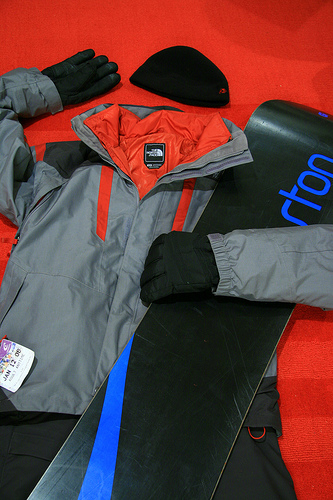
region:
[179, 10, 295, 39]
bright orange surface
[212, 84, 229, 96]
orange logo on black cap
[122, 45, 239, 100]
black cap on surface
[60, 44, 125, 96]
fingers on black gloves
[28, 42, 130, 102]
pair of black gloves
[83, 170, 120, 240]
orange lining on jacket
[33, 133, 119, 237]
black and gray jacket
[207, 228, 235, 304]
edge of gray jacket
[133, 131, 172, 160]
silver and black logo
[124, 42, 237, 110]
Black knitted ski hat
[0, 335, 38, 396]
Ski lift access tag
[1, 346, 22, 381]
Printed date of ski slope access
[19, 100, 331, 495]
Bottom of black snowboard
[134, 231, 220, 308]
Black snow glove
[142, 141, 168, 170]
Cloth jacket liner tag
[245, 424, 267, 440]
Red plastic jacket hook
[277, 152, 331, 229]
Painted snowboard identification label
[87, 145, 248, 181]
Snow jacket collar zipper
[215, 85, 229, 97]
Red logo on ski cap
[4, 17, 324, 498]
picture of snowboard with snoboaarding outfit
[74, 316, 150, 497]
blue strip on snowboard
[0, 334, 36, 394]
white ski lift ticket attached to jacket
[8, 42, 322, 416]
grey winter jacket with orange and black accents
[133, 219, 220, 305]
heavy black winter gloves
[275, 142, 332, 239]
blue lettering on black snowboard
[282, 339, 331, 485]
red striped blanket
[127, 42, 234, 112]
black knit winter hat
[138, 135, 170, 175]
black tag in collar of jacket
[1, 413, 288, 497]
black winter ski pants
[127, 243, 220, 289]
black glove on hand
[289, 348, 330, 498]
orange item next to black jacket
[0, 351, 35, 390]
date on the tag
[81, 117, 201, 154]
inside jacket is orange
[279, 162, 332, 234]
logo is in blue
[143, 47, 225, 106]
hat is black with orange on it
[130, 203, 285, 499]
hand holding a skateboard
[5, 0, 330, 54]
background is orange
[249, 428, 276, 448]
orange tag on jacket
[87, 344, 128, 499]
blue stripe on board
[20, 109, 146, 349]
Red, gray, and black coat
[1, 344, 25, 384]
White tag with black writing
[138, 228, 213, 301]
Black glove on snowboard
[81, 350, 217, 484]
Black snowboard with blue design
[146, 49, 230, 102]
Black knit cap with red logo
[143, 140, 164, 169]
Black label with white logo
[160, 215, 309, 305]
Empty coat sleeve wrapped around snowboard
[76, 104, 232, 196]
Coat laying on red background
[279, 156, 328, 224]
Blue lettering on black snowboard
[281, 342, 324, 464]
Two tone red material